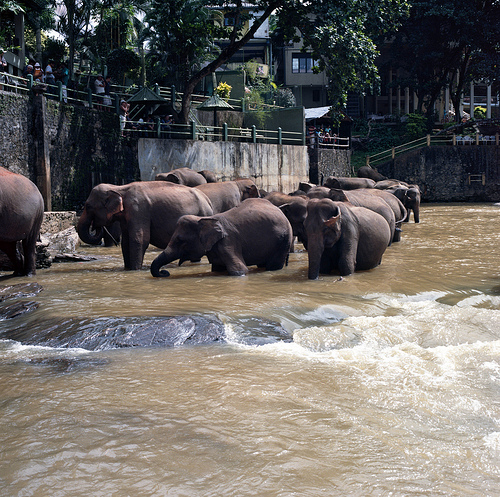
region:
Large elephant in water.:
[301, 178, 391, 305]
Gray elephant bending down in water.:
[152, 242, 258, 299]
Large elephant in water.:
[51, 184, 191, 271]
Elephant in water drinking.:
[393, 172, 413, 234]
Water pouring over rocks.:
[113, 311, 258, 353]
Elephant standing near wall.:
[22, 185, 119, 340]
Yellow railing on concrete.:
[363, 148, 420, 167]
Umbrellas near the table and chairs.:
[143, 77, 282, 136]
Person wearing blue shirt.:
[54, 63, 88, 87]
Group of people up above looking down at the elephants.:
[35, 70, 142, 117]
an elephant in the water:
[150, 196, 297, 284]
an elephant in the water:
[297, 199, 395, 288]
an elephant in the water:
[75, 175, 213, 268]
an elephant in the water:
[0, 163, 47, 277]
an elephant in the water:
[202, 173, 273, 203]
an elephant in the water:
[322, 181, 409, 239]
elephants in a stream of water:
[0, 156, 498, 495]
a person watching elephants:
[42, 57, 57, 82]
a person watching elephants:
[324, 128, 335, 140]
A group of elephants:
[56, 159, 455, 306]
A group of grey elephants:
[65, 164, 446, 310]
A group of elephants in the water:
[58, 166, 419, 386]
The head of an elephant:
[146, 207, 231, 310]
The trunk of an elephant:
[142, 234, 185, 294]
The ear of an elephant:
[175, 207, 237, 266]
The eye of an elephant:
[164, 227, 189, 251]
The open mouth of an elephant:
[163, 253, 198, 273]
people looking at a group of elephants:
[9, 54, 141, 134]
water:
[153, 358, 415, 443]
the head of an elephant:
[161, 207, 221, 272]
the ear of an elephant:
[192, 212, 227, 262]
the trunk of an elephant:
[146, 241, 179, 283]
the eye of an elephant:
[173, 230, 190, 248]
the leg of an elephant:
[116, 212, 150, 275]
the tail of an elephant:
[389, 195, 412, 230]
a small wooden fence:
[0, 67, 303, 145]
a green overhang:
[188, 87, 234, 114]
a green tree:
[304, 16, 384, 136]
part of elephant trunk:
[153, 249, 178, 282]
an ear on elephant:
[197, 217, 229, 247]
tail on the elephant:
[396, 192, 413, 232]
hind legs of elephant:
[5, 235, 47, 277]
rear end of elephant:
[253, 200, 295, 241]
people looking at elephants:
[23, 57, 113, 98]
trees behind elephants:
[405, 7, 475, 119]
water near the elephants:
[86, 296, 438, 455]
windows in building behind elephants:
[290, 50, 313, 71]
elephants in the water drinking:
[1, 145, 498, 326]